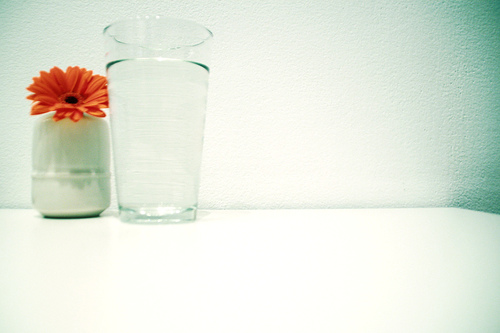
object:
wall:
[0, 1, 500, 209]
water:
[106, 57, 209, 215]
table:
[0, 206, 500, 333]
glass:
[100, 15, 214, 224]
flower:
[27, 65, 107, 119]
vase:
[31, 120, 109, 220]